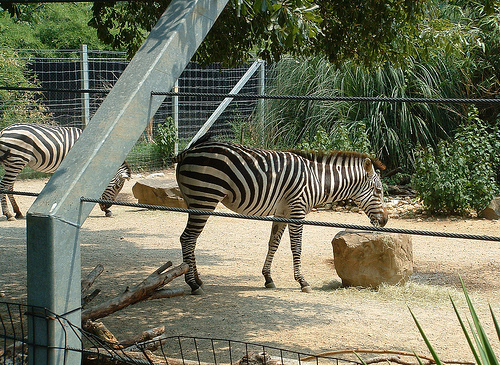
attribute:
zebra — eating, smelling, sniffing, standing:
[177, 138, 428, 247]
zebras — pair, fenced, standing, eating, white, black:
[15, 131, 403, 247]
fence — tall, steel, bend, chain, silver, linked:
[172, 76, 272, 139]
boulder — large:
[46, 54, 180, 166]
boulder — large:
[349, 235, 420, 301]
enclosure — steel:
[37, 51, 281, 143]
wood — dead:
[109, 269, 188, 317]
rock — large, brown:
[348, 233, 408, 269]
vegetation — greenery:
[384, 113, 498, 182]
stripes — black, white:
[223, 157, 307, 195]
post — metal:
[70, 42, 101, 123]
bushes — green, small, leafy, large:
[367, 61, 480, 207]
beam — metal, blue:
[30, 149, 131, 342]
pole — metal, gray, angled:
[62, 40, 107, 159]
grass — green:
[135, 126, 351, 162]